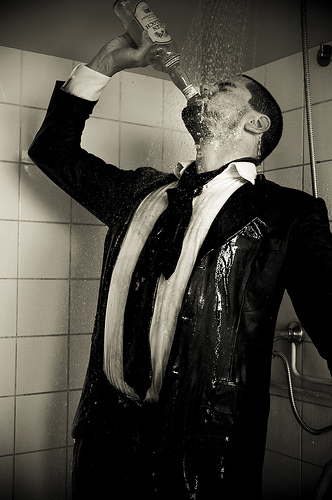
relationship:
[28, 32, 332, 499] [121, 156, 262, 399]
man has a tie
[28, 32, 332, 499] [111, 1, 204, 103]
man has a bottle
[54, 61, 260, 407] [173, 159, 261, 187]
shirt has collar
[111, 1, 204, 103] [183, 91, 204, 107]
bottle in mouth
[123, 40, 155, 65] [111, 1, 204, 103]
thumb on bottle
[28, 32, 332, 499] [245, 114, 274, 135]
man has an ear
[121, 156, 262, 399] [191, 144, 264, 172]
tie around neck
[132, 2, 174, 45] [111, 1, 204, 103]
label on bottle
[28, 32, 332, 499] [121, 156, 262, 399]
man has tie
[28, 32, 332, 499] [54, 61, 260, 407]
man has shirt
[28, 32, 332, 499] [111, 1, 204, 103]
man holding bottle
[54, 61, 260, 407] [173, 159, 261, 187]
shirt has a collar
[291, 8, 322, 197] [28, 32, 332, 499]
hose behind man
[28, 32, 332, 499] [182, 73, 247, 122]
man has a face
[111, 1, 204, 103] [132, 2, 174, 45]
bottle has a label